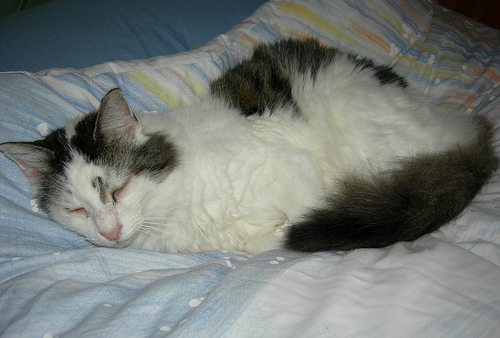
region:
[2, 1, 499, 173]
white yellow orange and blue striped pillow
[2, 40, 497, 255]
black and white cat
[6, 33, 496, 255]
cat sleeping on bed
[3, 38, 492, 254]
fluffy cat relaxing in bed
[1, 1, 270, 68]
light blue comforter on bed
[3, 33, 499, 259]
white and black fluffy cat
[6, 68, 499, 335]
blue and white blanket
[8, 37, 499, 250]
cat napping on bed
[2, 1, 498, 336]
bed with blue sheets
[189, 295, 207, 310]
white bleach stain on bedding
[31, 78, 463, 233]
black and white cat sleeping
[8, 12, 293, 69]
plain blue sheet on bed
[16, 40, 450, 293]
rainbow striped blanket on bed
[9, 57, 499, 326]
cat sleeping on rainbow striped blanket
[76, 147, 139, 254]
little bit of black on cats nose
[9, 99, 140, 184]
white stripe on cats head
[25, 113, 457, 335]
blanket is faded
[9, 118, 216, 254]
cats eyes are closed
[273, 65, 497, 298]
cat has black tail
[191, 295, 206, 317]
the spots are white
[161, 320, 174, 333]
the spots are white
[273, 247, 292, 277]
the spots are white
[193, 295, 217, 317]
the spots are white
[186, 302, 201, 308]
the spots are white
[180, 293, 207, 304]
the spots are white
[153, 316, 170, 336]
the spots are white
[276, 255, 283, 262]
the spots are white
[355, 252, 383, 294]
the blanket is fluffy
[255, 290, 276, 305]
the blanket is fluffy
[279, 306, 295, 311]
the blanket is fluffy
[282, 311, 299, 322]
the blanket is fluffy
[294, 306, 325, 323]
the blanket is fluffy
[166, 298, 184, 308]
the blanket is fluffy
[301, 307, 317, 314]
the blanket is fluffy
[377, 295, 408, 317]
the blanket is fluffy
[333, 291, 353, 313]
the blanket is fluffy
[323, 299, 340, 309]
the blanket is fluffy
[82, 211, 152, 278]
cat white a pink nose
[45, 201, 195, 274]
white whiskers on cats face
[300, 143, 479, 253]
black tail of cat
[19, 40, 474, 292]
cat sleeping on a comforter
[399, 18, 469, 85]
comforter with striped pattern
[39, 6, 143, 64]
blue pillow on bed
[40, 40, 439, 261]
white cat with scattered black fur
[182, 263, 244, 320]
white dots on comforter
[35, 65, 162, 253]
cat with eyes closed